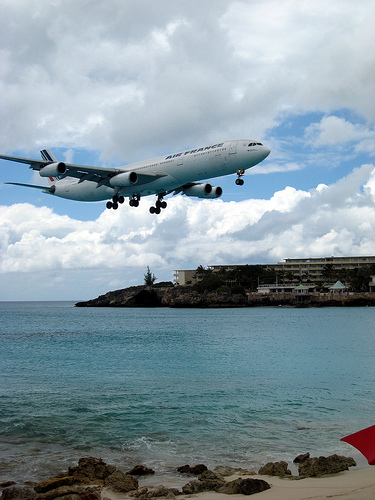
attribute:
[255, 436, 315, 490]
sand — white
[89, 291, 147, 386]
water — blue, calm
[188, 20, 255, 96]
cloud — here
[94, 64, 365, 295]
sky — clear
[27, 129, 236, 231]
airplane — landing, white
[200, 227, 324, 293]
building — big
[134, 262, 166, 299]
tree — here, small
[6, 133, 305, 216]
plane — here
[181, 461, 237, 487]
stone — here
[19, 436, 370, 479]
beach — here, sandy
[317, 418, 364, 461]
umbrella — red